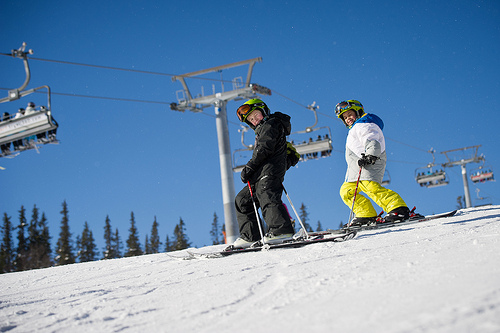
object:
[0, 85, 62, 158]
chairs